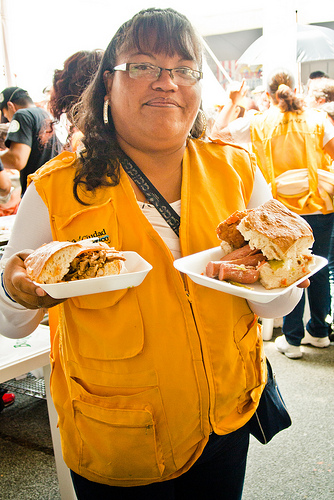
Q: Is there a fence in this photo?
A: No, there are no fences.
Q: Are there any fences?
A: No, there are no fences.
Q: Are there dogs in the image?
A: No, there are no dogs.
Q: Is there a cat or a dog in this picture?
A: No, there are no dogs or cats.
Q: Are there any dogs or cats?
A: No, there are no dogs or cats.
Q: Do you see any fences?
A: No, there are no fences.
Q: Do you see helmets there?
A: No, there are no helmets.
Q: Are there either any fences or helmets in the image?
A: No, there are no helmets or fences.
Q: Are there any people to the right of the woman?
A: Yes, there is a person to the right of the woman.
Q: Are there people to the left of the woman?
A: No, the person is to the right of the woman.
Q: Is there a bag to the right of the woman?
A: No, there is a person to the right of the woman.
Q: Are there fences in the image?
A: No, there are no fences.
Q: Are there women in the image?
A: Yes, there is a woman.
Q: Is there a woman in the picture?
A: Yes, there is a woman.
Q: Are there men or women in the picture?
A: Yes, there is a woman.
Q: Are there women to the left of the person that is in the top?
A: Yes, there is a woman to the left of the person.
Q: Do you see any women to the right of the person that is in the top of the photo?
A: No, the woman is to the left of the person.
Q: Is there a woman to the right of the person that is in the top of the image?
A: No, the woman is to the left of the person.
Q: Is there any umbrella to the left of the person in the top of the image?
A: No, there is a woman to the left of the person.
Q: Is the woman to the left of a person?
A: Yes, the woman is to the left of a person.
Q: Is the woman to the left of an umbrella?
A: No, the woman is to the left of a person.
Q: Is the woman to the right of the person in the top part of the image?
A: No, the woman is to the left of the person.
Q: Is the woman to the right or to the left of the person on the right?
A: The woman is to the left of the person.